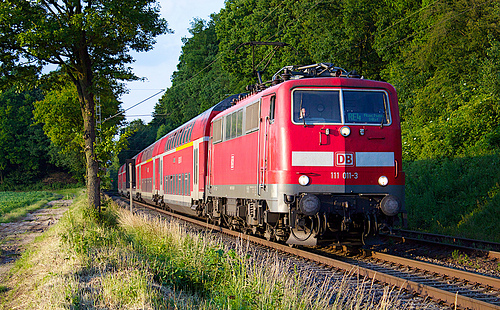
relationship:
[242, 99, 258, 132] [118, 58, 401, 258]
window of train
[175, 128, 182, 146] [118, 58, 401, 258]
train window of train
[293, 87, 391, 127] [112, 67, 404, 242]
window of train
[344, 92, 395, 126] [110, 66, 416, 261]
window of train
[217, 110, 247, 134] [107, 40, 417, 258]
window of train